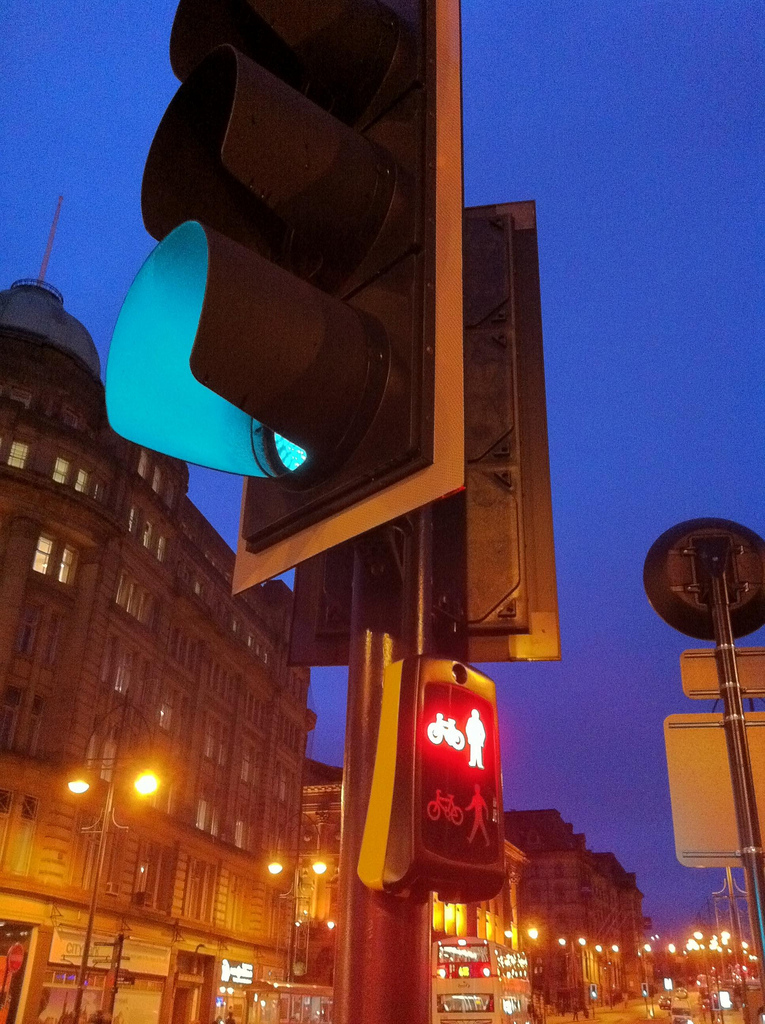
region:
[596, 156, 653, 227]
a view of sky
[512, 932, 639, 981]
a view of lights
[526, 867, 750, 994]
a view of street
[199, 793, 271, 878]
a view of windows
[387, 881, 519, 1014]
a view of doors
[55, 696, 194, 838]
lights on the top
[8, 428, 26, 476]
a window on a building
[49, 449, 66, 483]
a window on a building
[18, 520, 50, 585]
a window on a building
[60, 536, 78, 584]
a window on a building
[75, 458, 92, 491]
a window on a building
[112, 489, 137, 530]
a window on a building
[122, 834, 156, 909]
a window on a building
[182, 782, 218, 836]
a window on a building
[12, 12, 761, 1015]
deep blue sky over a city neighborhood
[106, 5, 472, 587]
traffic light shining with greenish-blue light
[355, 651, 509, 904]
traffic signal with standing person and bicycle illuminated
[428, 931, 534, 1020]
double-decker bus with lights and reflections of lights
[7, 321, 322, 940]
apartments with lit and unlit windows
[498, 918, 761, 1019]
round and white lights on top of lampposts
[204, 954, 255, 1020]
open store underneath brightly lit sign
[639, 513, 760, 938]
backs of round and oblong signs on dark pole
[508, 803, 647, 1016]
stately building with dark roof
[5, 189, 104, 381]
circular railing between dome and pole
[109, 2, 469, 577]
the traffic signal is green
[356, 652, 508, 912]
the pedestrian and bike signal is red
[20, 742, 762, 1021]
lamp posts are along the street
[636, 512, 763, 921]
the back of signs are on a pole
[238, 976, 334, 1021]
a bus stop is on the side of the street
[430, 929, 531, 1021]
the double decker bus is red and white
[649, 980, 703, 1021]
cars are traveling on the street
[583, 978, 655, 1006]
distant traffic signals are green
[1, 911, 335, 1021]
shops are along the street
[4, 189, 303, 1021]
a tower is on top of a building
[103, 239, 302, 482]
green light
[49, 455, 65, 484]
glass window on the building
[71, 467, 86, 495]
glass window on the building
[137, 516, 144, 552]
glass window on the building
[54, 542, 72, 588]
glass window on the building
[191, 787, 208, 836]
glass window on the building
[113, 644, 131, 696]
building has a window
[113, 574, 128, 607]
building has a window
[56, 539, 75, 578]
building has a window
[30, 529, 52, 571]
building has a window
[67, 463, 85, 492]
building has a windowbuilding has a window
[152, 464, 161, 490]
building has a window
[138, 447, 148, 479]
building has a window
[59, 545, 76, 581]
building has a window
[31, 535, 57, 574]
building has a window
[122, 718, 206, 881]
a light on the pole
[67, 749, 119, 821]
a light on the pole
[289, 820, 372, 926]
a light on the pole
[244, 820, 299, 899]
a light on the pole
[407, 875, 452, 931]
a light on the pole